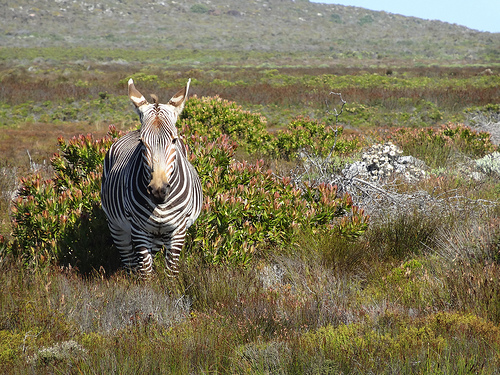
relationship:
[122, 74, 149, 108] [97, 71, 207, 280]
ear on zebra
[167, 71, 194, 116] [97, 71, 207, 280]
ear on zebra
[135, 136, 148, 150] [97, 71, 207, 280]
eye on zebra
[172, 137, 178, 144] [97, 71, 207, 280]
eye on zebra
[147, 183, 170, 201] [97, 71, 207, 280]
nose on zebra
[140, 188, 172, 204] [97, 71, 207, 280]
mouth on zebra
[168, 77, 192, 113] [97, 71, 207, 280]
ear of zebra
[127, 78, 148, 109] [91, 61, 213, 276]
ear of zebra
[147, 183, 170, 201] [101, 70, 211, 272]
nose of zebra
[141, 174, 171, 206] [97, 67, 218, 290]
nostril of zebra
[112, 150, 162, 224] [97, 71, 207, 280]
stripes of zebra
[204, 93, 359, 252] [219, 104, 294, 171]
bushes with flowers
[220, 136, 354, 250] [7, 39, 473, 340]
flowers growing field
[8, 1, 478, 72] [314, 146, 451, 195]
hill with rocks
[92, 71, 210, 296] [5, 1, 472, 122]
zebra in field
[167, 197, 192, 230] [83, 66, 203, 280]
stripes on zebra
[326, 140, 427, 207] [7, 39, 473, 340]
rocks on field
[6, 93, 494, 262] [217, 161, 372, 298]
flowers on bush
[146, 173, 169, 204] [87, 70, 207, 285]
nose on zebra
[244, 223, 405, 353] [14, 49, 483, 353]
grass in field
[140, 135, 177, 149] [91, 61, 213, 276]
eye of zebra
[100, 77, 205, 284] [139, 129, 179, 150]
zebra of eye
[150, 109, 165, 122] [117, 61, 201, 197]
hair on head